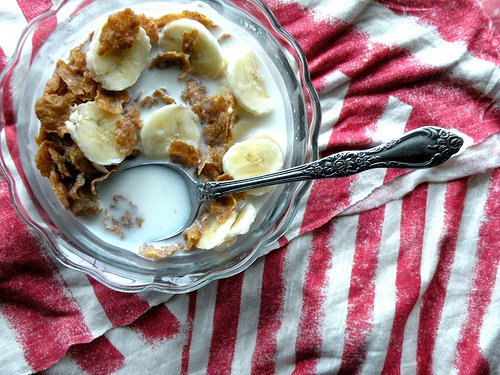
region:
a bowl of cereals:
[28, 9, 338, 261]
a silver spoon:
[116, 126, 462, 223]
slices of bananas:
[79, 92, 198, 152]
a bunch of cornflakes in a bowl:
[0, 2, 82, 127]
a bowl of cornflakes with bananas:
[48, 25, 278, 230]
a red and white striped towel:
[331, 208, 496, 350]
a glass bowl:
[9, 12, 307, 292]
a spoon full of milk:
[84, 175, 209, 243]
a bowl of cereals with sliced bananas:
[37, 35, 296, 266]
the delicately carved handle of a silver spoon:
[309, 129, 473, 184]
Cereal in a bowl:
[14, 16, 306, 260]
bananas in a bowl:
[54, 23, 340, 278]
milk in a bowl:
[12, 46, 317, 311]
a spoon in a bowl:
[10, 56, 334, 319]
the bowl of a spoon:
[79, 156, 228, 242]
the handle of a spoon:
[175, 129, 484, 213]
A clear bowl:
[30, 176, 349, 317]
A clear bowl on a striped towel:
[34, 194, 377, 349]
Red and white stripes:
[176, 237, 443, 347]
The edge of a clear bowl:
[53, 228, 297, 327]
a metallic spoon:
[323, 133, 488, 199]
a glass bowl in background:
[18, 11, 344, 302]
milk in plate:
[131, 47, 386, 242]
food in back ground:
[11, 2, 306, 317]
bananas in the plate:
[217, 121, 293, 216]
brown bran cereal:
[40, 31, 301, 286]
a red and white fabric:
[302, 197, 495, 338]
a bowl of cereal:
[26, 0, 337, 262]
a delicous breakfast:
[5, 2, 351, 339]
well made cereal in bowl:
[15, 3, 465, 350]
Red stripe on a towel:
[397, 190, 417, 307]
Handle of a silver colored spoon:
[321, 122, 464, 172]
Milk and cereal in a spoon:
[89, 172, 206, 230]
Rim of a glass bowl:
[284, 29, 324, 129]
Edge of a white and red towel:
[0, 327, 119, 370]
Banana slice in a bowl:
[138, 111, 209, 156]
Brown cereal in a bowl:
[39, 81, 91, 196]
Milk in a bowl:
[147, 70, 177, 87]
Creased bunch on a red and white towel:
[316, 11, 435, 96]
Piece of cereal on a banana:
[83, 9, 153, 82]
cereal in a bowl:
[23, 14, 346, 279]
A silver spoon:
[70, 109, 446, 236]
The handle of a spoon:
[196, 120, 462, 197]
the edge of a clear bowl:
[34, 198, 266, 333]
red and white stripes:
[198, 280, 457, 360]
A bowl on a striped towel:
[95, 174, 380, 345]